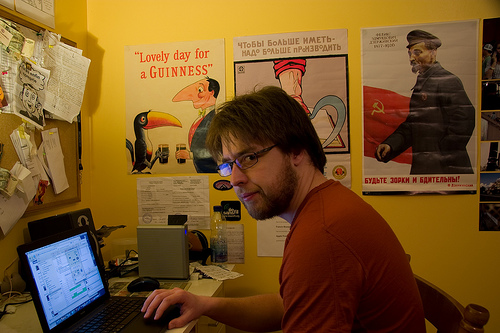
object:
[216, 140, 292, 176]
eyeglasses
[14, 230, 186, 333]
laptop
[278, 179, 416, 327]
shirt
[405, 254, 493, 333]
chair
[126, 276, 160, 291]
mouse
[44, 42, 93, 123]
papers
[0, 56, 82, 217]
cork board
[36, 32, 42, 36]
pin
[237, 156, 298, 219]
beard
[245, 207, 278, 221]
chin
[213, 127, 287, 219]
face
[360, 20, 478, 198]
poster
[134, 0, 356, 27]
wall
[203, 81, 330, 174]
hair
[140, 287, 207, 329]
hand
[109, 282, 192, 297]
pad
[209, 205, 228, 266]
bottle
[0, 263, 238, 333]
desk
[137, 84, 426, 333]
man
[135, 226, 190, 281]
modem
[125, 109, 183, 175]
toucan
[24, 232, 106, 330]
monitor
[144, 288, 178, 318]
fingers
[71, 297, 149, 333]
keyboard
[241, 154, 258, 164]
eyes